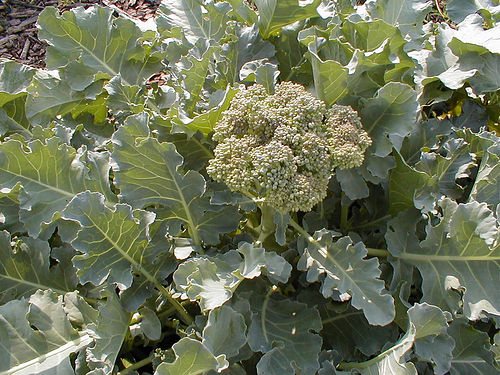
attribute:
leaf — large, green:
[294, 230, 394, 329]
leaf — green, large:
[31, 2, 169, 111]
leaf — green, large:
[231, 179, 446, 346]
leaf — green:
[148, 253, 278, 324]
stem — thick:
[363, 242, 499, 260]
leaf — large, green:
[236, 283, 333, 373]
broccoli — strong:
[200, 74, 374, 211]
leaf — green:
[48, 109, 320, 296]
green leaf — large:
[382, 203, 498, 316]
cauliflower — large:
[207, 80, 372, 214]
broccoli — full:
[198, 74, 382, 218]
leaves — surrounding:
[358, 30, 479, 218]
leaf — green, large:
[237, 237, 294, 292]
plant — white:
[1, 4, 498, 372]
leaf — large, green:
[85, 130, 212, 265]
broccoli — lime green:
[205, 69, 365, 226]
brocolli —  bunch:
[207, 81, 371, 243]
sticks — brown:
[13, 11, 67, 76]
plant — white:
[205, 78, 372, 215]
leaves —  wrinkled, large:
[2, 3, 484, 373]